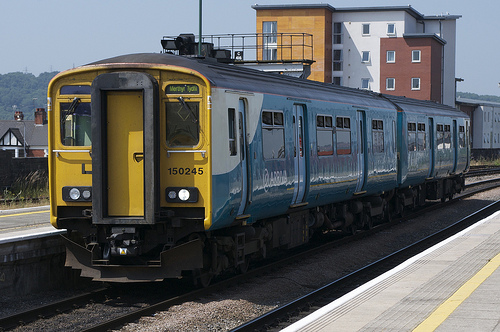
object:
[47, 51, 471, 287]
train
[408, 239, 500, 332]
line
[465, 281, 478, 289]
yellow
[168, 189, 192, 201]
headlights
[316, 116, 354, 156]
windows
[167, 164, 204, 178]
numbers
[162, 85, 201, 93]
digital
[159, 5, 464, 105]
building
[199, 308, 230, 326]
rocks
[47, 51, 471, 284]
track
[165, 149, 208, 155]
silver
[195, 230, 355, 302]
shadow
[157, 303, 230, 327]
pebbles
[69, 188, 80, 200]
white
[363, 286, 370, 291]
white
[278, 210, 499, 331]
platform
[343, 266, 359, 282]
blue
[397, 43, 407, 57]
red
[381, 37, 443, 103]
small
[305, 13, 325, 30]
orange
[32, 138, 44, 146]
grey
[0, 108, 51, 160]
house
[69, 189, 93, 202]
light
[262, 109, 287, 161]
window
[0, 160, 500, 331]
rails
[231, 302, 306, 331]
steel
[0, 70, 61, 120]
hill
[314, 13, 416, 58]
colorful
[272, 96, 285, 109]
blue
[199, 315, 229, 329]
gravel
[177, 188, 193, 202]
headlight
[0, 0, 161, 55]
sky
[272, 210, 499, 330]
ground